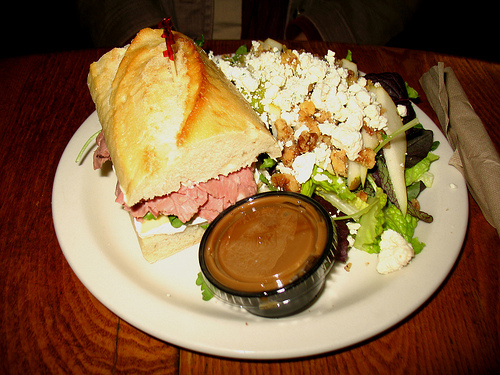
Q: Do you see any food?
A: Yes, there is food.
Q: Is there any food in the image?
A: Yes, there is food.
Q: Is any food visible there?
A: Yes, there is food.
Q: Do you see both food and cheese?
A: Yes, there are both food and cheese.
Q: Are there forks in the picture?
A: No, there are no forks.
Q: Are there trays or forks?
A: No, there are no forks or trays.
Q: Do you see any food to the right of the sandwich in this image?
A: Yes, there is food to the right of the sandwich.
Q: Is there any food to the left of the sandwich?
A: No, the food is to the right of the sandwich.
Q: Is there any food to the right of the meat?
A: Yes, there is food to the right of the meat.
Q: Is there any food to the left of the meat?
A: No, the food is to the right of the meat.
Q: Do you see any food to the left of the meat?
A: No, the food is to the right of the meat.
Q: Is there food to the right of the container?
A: Yes, there is food to the right of the container.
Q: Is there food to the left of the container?
A: No, the food is to the right of the container.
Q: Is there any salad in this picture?
A: Yes, there is salad.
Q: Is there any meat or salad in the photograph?
A: Yes, there is salad.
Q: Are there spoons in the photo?
A: No, there are no spoons.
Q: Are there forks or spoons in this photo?
A: No, there are no spoons or forks.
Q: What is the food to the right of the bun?
A: The food is salad.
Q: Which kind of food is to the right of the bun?
A: The food is salad.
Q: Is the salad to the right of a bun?
A: Yes, the salad is to the right of a bun.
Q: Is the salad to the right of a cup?
A: No, the salad is to the right of a bun.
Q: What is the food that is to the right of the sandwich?
A: The food is salad.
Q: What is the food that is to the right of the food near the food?
A: The food is salad.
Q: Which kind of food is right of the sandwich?
A: The food is salad.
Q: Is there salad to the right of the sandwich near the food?
A: Yes, there is salad to the right of the sandwich.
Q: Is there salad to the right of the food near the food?
A: Yes, there is salad to the right of the sandwich.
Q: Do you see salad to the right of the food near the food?
A: Yes, there is salad to the right of the sandwich.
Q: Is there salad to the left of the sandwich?
A: No, the salad is to the right of the sandwich.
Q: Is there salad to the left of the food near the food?
A: No, the salad is to the right of the sandwich.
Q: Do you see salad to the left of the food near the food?
A: No, the salad is to the right of the sandwich.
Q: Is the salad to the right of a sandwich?
A: Yes, the salad is to the right of a sandwich.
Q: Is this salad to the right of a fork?
A: No, the salad is to the right of a sandwich.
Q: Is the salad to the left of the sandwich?
A: No, the salad is to the right of the sandwich.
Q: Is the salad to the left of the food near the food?
A: No, the salad is to the right of the sandwich.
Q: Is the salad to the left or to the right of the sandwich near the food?
A: The salad is to the right of the sandwich.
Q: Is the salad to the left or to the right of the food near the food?
A: The salad is to the right of the sandwich.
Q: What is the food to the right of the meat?
A: The food is salad.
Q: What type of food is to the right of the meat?
A: The food is salad.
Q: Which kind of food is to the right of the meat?
A: The food is salad.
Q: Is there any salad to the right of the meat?
A: Yes, there is salad to the right of the meat.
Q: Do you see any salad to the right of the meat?
A: Yes, there is salad to the right of the meat.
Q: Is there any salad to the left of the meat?
A: No, the salad is to the right of the meat.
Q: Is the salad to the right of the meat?
A: Yes, the salad is to the right of the meat.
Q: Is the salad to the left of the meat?
A: No, the salad is to the right of the meat.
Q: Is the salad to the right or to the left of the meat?
A: The salad is to the right of the meat.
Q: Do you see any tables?
A: Yes, there is a table.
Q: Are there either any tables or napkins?
A: Yes, there is a table.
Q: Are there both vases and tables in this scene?
A: No, there is a table but no vases.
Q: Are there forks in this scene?
A: No, there are no forks.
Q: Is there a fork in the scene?
A: No, there are no forks.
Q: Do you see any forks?
A: No, there are no forks.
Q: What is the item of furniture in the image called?
A: The piece of furniture is a table.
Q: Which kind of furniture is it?
A: The piece of furniture is a table.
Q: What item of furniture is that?
A: This is a table.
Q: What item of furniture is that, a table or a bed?
A: This is a table.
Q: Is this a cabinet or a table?
A: This is a table.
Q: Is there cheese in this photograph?
A: Yes, there is cheese.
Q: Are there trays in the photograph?
A: No, there are no trays.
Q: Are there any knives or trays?
A: No, there are no trays or knives.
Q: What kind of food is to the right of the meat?
A: The food is cheese.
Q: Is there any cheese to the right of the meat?
A: Yes, there is cheese to the right of the meat.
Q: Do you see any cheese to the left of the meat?
A: No, the cheese is to the right of the meat.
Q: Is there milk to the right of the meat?
A: No, there is cheese to the right of the meat.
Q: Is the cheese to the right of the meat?
A: Yes, the cheese is to the right of the meat.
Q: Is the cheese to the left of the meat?
A: No, the cheese is to the right of the meat.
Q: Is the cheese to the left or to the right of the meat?
A: The cheese is to the right of the meat.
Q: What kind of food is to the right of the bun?
A: The food is cheese.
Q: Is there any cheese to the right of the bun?
A: Yes, there is cheese to the right of the bun.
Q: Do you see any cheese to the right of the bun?
A: Yes, there is cheese to the right of the bun.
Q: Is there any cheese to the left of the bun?
A: No, the cheese is to the right of the bun.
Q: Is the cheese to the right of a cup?
A: No, the cheese is to the right of the bun.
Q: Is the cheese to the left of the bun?
A: No, the cheese is to the right of the bun.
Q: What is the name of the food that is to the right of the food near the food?
A: The food is cheese.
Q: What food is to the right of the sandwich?
A: The food is cheese.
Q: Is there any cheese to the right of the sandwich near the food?
A: Yes, there is cheese to the right of the sandwich.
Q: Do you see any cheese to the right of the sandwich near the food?
A: Yes, there is cheese to the right of the sandwich.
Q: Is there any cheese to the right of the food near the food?
A: Yes, there is cheese to the right of the sandwich.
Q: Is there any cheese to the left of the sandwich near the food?
A: No, the cheese is to the right of the sandwich.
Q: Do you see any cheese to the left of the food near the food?
A: No, the cheese is to the right of the sandwich.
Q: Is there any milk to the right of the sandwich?
A: No, there is cheese to the right of the sandwich.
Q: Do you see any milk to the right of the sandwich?
A: No, there is cheese to the right of the sandwich.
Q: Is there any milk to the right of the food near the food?
A: No, there is cheese to the right of the sandwich.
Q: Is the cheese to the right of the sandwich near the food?
A: Yes, the cheese is to the right of the sandwich.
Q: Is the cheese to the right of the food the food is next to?
A: Yes, the cheese is to the right of the sandwich.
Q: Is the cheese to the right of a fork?
A: No, the cheese is to the right of the sandwich.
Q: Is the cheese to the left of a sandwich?
A: No, the cheese is to the right of a sandwich.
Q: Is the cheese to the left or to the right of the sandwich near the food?
A: The cheese is to the right of the sandwich.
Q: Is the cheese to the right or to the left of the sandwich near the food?
A: The cheese is to the right of the sandwich.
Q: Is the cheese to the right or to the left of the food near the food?
A: The cheese is to the right of the sandwich.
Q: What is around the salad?
A: The cheese is around the salad.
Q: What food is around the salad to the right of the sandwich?
A: The food is cheese.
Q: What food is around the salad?
A: The food is cheese.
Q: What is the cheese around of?
A: The cheese is around the salad.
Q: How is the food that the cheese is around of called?
A: The food is salad.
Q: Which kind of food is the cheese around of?
A: The cheese is around the salad.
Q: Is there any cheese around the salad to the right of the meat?
A: Yes, there is cheese around the salad.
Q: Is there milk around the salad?
A: No, there is cheese around the salad.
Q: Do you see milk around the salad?
A: No, there is cheese around the salad.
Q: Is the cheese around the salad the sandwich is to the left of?
A: Yes, the cheese is around the salad.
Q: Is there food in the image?
A: Yes, there is food.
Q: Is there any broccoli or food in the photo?
A: Yes, there is food.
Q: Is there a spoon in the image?
A: No, there are no spoons.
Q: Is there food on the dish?
A: Yes, there is food on the dish.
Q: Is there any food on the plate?
A: Yes, there is food on the plate.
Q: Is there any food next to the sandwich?
A: Yes, there is food next to the sandwich.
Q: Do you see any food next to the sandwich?
A: Yes, there is food next to the sandwich.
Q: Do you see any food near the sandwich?
A: Yes, there is food near the sandwich.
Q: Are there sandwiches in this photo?
A: Yes, there is a sandwich.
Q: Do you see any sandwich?
A: Yes, there is a sandwich.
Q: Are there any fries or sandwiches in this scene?
A: Yes, there is a sandwich.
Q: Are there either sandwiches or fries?
A: Yes, there is a sandwich.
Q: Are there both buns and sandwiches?
A: Yes, there are both a sandwich and a bun.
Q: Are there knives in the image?
A: No, there are no knives.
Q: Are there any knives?
A: No, there are no knives.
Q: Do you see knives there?
A: No, there are no knives.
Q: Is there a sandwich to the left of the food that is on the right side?
A: Yes, there is a sandwich to the left of the food.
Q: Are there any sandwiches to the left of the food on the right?
A: Yes, there is a sandwich to the left of the food.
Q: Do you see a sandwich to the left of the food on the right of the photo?
A: Yes, there is a sandwich to the left of the food.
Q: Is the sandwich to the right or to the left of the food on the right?
A: The sandwich is to the left of the food.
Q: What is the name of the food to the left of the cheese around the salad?
A: The food is a sandwich.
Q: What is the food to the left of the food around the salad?
A: The food is a sandwich.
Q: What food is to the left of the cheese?
A: The food is a sandwich.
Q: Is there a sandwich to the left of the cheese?
A: Yes, there is a sandwich to the left of the cheese.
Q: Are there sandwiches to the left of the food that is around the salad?
A: Yes, there is a sandwich to the left of the cheese.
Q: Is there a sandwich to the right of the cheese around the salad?
A: No, the sandwich is to the left of the cheese.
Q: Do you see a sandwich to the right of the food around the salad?
A: No, the sandwich is to the left of the cheese.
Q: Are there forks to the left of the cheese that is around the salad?
A: No, there is a sandwich to the left of the cheese.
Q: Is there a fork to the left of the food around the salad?
A: No, there is a sandwich to the left of the cheese.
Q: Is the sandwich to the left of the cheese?
A: Yes, the sandwich is to the left of the cheese.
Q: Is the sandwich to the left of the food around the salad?
A: Yes, the sandwich is to the left of the cheese.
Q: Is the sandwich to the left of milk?
A: No, the sandwich is to the left of the cheese.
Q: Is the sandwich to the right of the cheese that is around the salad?
A: No, the sandwich is to the left of the cheese.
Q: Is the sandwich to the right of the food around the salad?
A: No, the sandwich is to the left of the cheese.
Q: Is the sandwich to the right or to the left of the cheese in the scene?
A: The sandwich is to the left of the cheese.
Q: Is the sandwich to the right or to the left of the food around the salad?
A: The sandwich is to the left of the cheese.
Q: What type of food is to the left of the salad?
A: The food is a sandwich.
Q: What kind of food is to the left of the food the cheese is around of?
A: The food is a sandwich.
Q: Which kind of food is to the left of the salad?
A: The food is a sandwich.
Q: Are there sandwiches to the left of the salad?
A: Yes, there is a sandwich to the left of the salad.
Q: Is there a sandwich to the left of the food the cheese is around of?
A: Yes, there is a sandwich to the left of the salad.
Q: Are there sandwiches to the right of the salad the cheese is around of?
A: No, the sandwich is to the left of the salad.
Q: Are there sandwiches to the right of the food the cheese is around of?
A: No, the sandwich is to the left of the salad.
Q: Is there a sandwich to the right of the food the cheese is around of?
A: No, the sandwich is to the left of the salad.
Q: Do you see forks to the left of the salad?
A: No, there is a sandwich to the left of the salad.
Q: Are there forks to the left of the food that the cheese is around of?
A: No, there is a sandwich to the left of the salad.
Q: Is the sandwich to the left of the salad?
A: Yes, the sandwich is to the left of the salad.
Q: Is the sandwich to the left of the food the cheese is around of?
A: Yes, the sandwich is to the left of the salad.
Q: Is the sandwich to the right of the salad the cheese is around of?
A: No, the sandwich is to the left of the salad.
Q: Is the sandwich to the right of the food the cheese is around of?
A: No, the sandwich is to the left of the salad.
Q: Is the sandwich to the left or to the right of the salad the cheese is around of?
A: The sandwich is to the left of the salad.